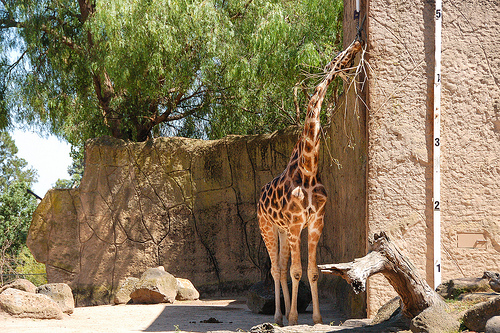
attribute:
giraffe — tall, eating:
[250, 35, 374, 328]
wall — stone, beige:
[330, 0, 499, 331]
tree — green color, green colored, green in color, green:
[1, 5, 350, 140]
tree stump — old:
[316, 229, 499, 330]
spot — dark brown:
[300, 154, 314, 171]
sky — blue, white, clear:
[0, 0, 227, 196]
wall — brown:
[30, 119, 330, 302]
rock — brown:
[131, 264, 182, 301]